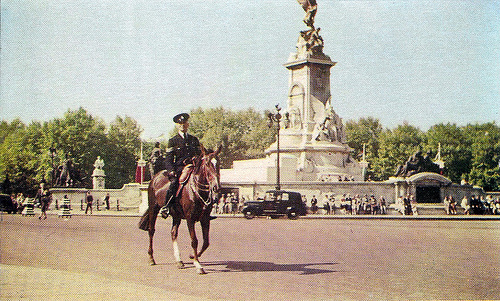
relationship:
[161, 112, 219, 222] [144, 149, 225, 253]
man on horse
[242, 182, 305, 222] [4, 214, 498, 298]
car on street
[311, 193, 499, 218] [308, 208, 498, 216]
people on steps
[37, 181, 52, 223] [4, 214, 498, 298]
person crossing street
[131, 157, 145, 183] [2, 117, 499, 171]
flag in park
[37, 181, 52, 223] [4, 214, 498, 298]
person cross street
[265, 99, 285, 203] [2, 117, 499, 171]
lamp in park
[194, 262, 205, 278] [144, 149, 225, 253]
hoof of horse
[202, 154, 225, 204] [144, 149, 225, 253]
head of horse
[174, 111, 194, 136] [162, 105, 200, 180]
head of man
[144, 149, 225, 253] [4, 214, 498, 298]
horse on road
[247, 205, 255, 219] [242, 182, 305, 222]
tire of car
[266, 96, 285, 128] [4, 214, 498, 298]
lights of street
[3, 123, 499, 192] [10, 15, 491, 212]
trees in background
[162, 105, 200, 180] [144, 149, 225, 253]
man on horse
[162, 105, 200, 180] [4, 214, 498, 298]
man in parade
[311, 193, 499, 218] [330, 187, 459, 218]
people in group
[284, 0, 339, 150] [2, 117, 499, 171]
monument in park